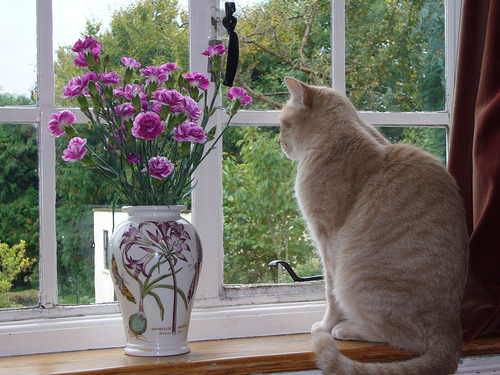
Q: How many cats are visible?
A: One.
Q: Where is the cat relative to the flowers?
A: To the right.